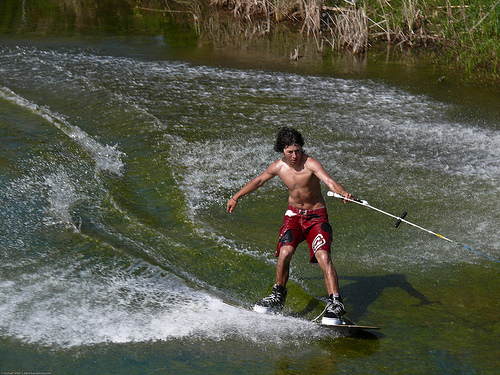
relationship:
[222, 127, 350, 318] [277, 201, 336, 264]
man wearing shorts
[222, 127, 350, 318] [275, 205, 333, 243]
man wearing shorts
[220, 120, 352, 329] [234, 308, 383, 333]
man on board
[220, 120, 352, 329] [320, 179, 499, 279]
man holding line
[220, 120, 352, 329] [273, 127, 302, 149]
man with hair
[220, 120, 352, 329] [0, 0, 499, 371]
man in water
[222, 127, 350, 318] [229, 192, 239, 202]
man with band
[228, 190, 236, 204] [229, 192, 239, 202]
wrist with band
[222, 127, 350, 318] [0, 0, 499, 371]
man on water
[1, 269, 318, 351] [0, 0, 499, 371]
foam on water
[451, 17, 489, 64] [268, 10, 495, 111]
grass on shoreline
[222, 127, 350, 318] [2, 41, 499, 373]
man on river